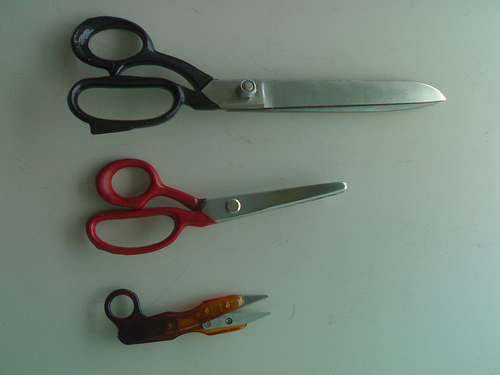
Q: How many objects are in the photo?
A: Three.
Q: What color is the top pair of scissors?
A: Black.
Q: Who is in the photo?
A: No one.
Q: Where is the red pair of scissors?
A: In the middle.